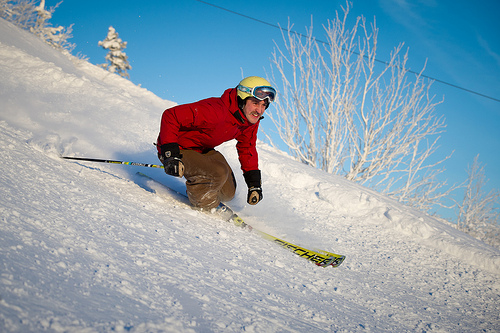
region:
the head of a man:
[238, 73, 279, 125]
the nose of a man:
[253, 101, 263, 115]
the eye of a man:
[248, 97, 260, 108]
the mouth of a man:
[248, 109, 263, 119]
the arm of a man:
[156, 96, 221, 145]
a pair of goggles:
[233, 80, 278, 105]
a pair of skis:
[127, 164, 352, 273]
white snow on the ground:
[0, 14, 493, 330]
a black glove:
[156, 138, 193, 177]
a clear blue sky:
[0, 0, 498, 257]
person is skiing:
[55, 75, 347, 270]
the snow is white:
[0, 18, 499, 331]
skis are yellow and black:
[225, 209, 347, 271]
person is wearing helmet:
[238, 76, 276, 103]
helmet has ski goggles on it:
[236, 85, 276, 101]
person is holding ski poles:
[52, 146, 264, 203]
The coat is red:
[156, 91, 263, 175]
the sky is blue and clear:
[0, 0, 496, 238]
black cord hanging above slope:
[198, 1, 499, 101]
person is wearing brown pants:
[156, 143, 238, 212]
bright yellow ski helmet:
[226, 65, 282, 109]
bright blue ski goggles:
[234, 80, 276, 102]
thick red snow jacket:
[146, 84, 274, 179]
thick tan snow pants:
[154, 132, 241, 218]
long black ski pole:
[53, 147, 193, 184]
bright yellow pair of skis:
[172, 188, 354, 282]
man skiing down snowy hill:
[44, 58, 360, 275]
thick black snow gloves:
[138, 134, 271, 209]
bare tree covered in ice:
[250, 2, 459, 214]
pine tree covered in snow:
[79, 11, 144, 94]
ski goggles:
[253, 82, 285, 110]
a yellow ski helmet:
[236, 71, 278, 105]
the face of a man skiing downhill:
[231, 74, 281, 129]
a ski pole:
[55, 143, 172, 186]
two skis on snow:
[212, 199, 350, 278]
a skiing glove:
[156, 140, 188, 180]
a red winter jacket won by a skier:
[160, 86, 270, 171]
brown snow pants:
[161, 146, 244, 211]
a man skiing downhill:
[90, 71, 345, 279]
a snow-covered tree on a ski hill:
[284, 40, 421, 191]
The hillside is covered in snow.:
[1, 15, 498, 331]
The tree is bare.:
[244, 7, 434, 190]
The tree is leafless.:
[251, 3, 438, 198]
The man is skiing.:
[41, 60, 353, 301]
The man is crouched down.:
[28, 54, 348, 291]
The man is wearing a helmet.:
[140, 64, 288, 236]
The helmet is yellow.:
[234, 70, 282, 129]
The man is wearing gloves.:
[153, 65, 281, 225]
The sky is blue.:
[6, 2, 498, 238]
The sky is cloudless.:
[6, 0, 498, 225]